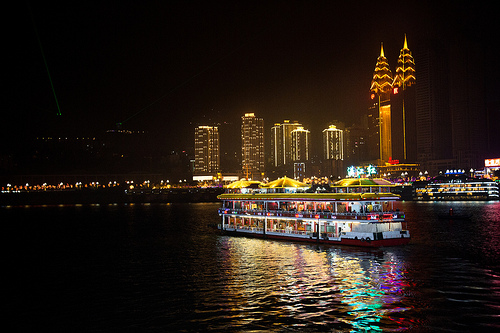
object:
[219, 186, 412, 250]
boat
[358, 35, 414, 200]
building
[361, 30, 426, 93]
light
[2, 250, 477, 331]
water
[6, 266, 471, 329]
water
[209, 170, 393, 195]
lights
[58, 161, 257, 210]
lights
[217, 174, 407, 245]
ship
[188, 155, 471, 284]
boat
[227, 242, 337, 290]
reflection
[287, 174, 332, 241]
lights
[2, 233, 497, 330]
water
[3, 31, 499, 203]
city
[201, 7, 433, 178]
buildings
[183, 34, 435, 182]
buildings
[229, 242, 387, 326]
reflection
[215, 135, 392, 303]
lights reflected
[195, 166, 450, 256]
boat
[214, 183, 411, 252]
boat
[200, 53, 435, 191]
buildings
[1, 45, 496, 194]
lights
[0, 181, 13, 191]
light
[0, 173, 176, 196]
lights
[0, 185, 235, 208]
dock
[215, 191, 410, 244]
ship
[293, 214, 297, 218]
light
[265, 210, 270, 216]
light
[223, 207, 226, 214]
light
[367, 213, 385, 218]
light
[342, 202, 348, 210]
light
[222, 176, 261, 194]
umbrella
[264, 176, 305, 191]
umbrella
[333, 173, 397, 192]
umbrella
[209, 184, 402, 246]
boat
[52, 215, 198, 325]
water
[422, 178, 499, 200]
boat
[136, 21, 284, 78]
dark sky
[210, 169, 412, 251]
boat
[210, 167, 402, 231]
lights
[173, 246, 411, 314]
water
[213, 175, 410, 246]
boat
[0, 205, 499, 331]
river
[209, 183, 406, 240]
people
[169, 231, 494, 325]
ripples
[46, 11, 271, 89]
sky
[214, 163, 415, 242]
boat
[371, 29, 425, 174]
tall building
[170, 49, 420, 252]
buildings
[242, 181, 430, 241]
boat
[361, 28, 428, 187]
building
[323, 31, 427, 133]
skyscraper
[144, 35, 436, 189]
buildings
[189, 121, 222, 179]
lit building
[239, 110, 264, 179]
lit building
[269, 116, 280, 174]
lit building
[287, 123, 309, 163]
lit building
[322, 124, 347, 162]
lit building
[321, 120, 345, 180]
building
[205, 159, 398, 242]
boat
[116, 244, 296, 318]
water